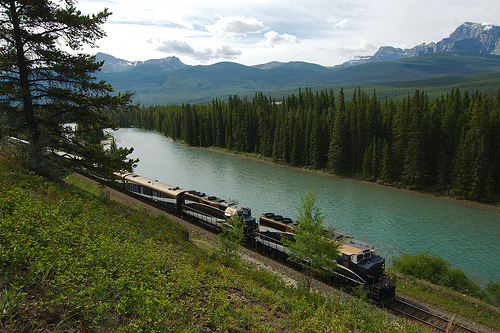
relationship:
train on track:
[5, 135, 398, 306] [405, 295, 446, 327]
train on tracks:
[5, 135, 398, 306] [372, 291, 484, 330]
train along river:
[8, 132, 396, 316] [42, 112, 497, 307]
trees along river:
[449, 82, 498, 199] [129, 135, 493, 285]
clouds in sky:
[139, 2, 291, 52] [10, 1, 496, 56]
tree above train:
[0, 0, 141, 182] [8, 132, 396, 316]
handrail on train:
[372, 275, 399, 302] [8, 132, 396, 316]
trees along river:
[106, 79, 499, 206] [61, 121, 497, 293]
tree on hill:
[2, 1, 141, 198] [0, 136, 500, 332]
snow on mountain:
[477, 20, 496, 32] [313, 22, 499, 69]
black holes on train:
[263, 209, 294, 227] [8, 132, 396, 316]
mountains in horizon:
[86, 17, 499, 70] [0, 4, 500, 91]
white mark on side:
[258, 237, 283, 254] [258, 220, 361, 290]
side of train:
[258, 220, 361, 290] [8, 132, 396, 316]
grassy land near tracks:
[0, 162, 428, 331] [83, 168, 490, 331]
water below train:
[43, 116, 496, 288] [8, 132, 396, 316]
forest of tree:
[76, 88, 496, 201] [326, 101, 355, 172]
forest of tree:
[76, 88, 496, 201] [447, 123, 482, 194]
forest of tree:
[76, 88, 496, 201] [167, 111, 182, 142]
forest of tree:
[76, 88, 496, 201] [137, 104, 151, 132]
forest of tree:
[76, 88, 496, 201] [333, 85, 348, 109]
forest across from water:
[76, 88, 496, 201] [43, 116, 496, 288]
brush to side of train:
[390, 251, 500, 326] [4, 135, 399, 301]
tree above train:
[0, 0, 141, 182] [4, 135, 399, 301]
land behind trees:
[136, 57, 497, 92] [122, 87, 494, 204]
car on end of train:
[244, 196, 455, 311] [8, 132, 396, 316]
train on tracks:
[8, 132, 396, 316] [373, 290, 495, 331]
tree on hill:
[0, 0, 141, 182] [4, 147, 419, 328]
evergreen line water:
[139, 105, 151, 130] [147, 118, 403, 254]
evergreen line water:
[180, 101, 196, 146] [147, 118, 403, 254]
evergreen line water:
[307, 106, 329, 169] [147, 118, 403, 254]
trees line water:
[449, 82, 498, 199] [147, 118, 403, 254]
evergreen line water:
[250, 97, 271, 159] [147, 118, 403, 254]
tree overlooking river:
[0, 0, 141, 182] [54, 110, 482, 294]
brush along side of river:
[383, 243, 479, 301] [54, 110, 482, 294]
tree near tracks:
[275, 174, 339, 297] [386, 281, 448, 329]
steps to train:
[364, 276, 394, 310] [8, 132, 396, 316]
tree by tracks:
[277, 185, 349, 292] [255, 219, 475, 331]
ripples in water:
[292, 161, 360, 197] [43, 116, 496, 288]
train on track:
[8, 132, 396, 316] [391, 298, 468, 331]